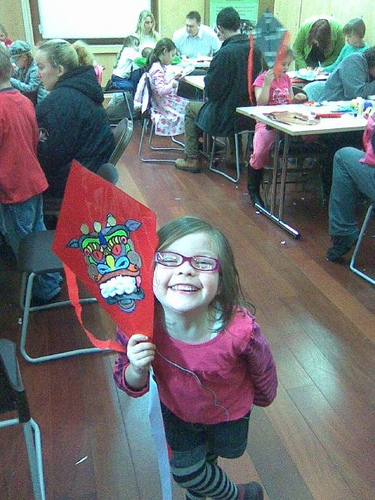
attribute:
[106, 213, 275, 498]
girl — proud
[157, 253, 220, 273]
glasses — purple, pink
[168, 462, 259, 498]
socks — blue, striped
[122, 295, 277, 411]
shirt — pink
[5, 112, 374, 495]
floors — brown, wooden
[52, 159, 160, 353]
kite — red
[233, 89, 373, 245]
table — white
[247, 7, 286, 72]
kite — gray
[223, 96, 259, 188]
chair — black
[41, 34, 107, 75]
hair — blonde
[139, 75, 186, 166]
chair — black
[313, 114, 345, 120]
tool — red